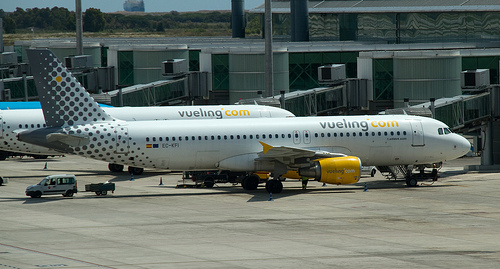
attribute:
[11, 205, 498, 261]
pavement — gray, white, airport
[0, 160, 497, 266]
ground — airport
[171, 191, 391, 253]
pavement — airport, gray, white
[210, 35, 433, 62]
buildings — white, green, colored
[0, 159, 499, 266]
tarmac — grey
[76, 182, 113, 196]
cart — attached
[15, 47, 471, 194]
plane — white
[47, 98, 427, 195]
plane — airline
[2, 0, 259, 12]
sky — daytime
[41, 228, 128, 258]
square — big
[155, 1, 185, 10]
sky — clear, blue, cloudless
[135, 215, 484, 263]
pavement — white, airport, gray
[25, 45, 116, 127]
stabilizer — vertical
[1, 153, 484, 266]
pavement — gray, white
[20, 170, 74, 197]
car — white